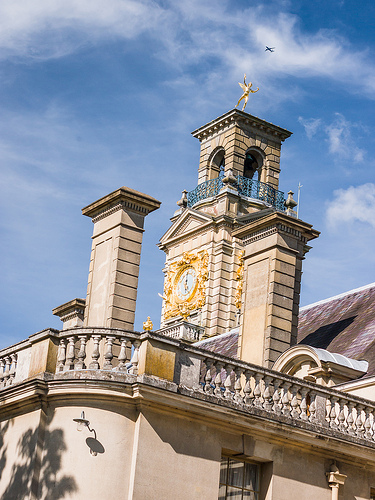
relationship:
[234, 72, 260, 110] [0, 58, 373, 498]
statue on building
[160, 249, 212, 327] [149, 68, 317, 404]
clock on building tower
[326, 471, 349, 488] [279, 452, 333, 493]
watersprout on wall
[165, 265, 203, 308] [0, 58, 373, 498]
clock face on building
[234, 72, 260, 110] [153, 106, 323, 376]
statue on building tower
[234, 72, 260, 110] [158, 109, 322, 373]
statue on tower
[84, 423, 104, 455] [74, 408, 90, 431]
shadow of lamp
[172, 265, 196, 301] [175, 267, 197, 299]
clock has clock face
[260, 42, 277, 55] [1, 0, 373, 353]
airplane flying in sky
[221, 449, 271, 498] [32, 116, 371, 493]
window in building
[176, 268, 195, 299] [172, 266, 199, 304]
numbers on clock face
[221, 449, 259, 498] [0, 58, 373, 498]
window in side building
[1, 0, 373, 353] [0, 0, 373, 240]
sky with clouds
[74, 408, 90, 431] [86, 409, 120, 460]
lamp on wall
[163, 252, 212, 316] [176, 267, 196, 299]
frame surrounding clock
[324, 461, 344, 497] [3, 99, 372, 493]
pipes on building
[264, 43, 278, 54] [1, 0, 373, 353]
airplane in sky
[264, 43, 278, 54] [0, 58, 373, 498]
airplane above building